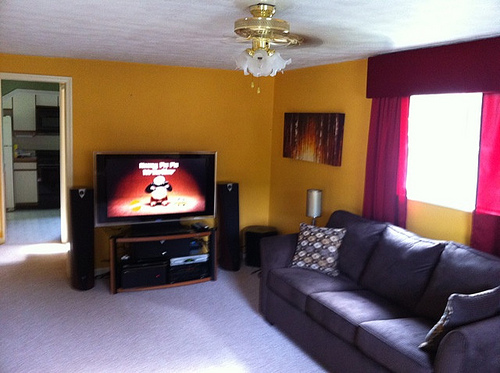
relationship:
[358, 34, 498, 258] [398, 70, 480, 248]
curtains covering window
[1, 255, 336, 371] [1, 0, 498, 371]
carpet in living living room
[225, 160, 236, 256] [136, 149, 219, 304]
speaker to left of a tv